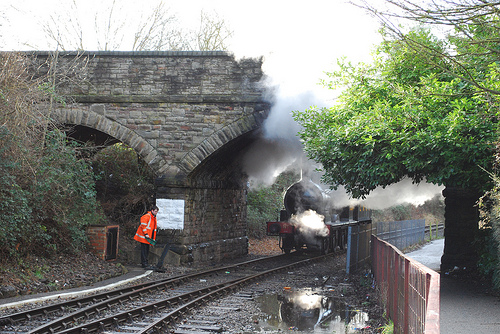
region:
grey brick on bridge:
[139, 128, 159, 138]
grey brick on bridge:
[128, 107, 143, 120]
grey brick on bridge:
[90, 102, 107, 117]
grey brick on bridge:
[171, 108, 185, 118]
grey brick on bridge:
[188, 150, 198, 164]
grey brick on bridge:
[201, 140, 215, 152]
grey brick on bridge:
[210, 131, 224, 147]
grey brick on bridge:
[86, 108, 96, 125]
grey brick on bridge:
[67, 106, 76, 123]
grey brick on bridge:
[111, 84, 126, 95]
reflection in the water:
[262, 285, 360, 332]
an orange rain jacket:
[135, 212, 160, 245]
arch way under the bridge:
[22, 107, 160, 257]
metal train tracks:
[4, 250, 331, 332]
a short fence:
[372, 233, 439, 329]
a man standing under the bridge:
[134, 203, 158, 263]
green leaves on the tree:
[299, 13, 497, 190]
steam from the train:
[286, 208, 326, 240]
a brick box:
[89, 224, 119, 257]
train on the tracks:
[267, 167, 352, 259]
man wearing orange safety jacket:
[130, 201, 170, 262]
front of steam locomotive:
[271, 150, 329, 265]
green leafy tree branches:
[300, 55, 403, 186]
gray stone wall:
[120, 57, 218, 98]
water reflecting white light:
[251, 271, 362, 327]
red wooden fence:
[378, 241, 461, 322]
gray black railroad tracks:
[101, 278, 221, 323]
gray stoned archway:
[51, 100, 178, 180]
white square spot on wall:
[152, 193, 195, 233]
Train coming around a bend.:
[275, 164, 445, 262]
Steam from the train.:
[240, 66, 442, 236]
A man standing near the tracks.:
[130, 203, 160, 269]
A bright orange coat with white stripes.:
[132, 210, 157, 245]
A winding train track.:
[20, 220, 445, 332]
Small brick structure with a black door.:
[75, 221, 116, 263]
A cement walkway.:
[402, 233, 497, 332]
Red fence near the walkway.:
[370, 234, 440, 333]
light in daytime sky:
[0, 2, 485, 50]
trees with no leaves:
[2, 1, 241, 48]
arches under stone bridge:
[2, 51, 299, 270]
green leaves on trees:
[296, 19, 496, 201]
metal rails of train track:
[7, 255, 299, 332]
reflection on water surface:
[264, 285, 357, 332]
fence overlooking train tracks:
[365, 231, 441, 331]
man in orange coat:
[134, 204, 159, 264]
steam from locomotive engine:
[254, 64, 361, 195]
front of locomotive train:
[284, 179, 327, 224]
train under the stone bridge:
[270, 165, 357, 261]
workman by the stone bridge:
[134, 203, 166, 273]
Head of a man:
[148, 203, 162, 217]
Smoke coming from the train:
[258, 80, 422, 235]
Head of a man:
[151, 205, 159, 216]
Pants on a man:
[140, 241, 152, 268]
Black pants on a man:
[136, 241, 149, 266]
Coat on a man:
[132, 210, 161, 246]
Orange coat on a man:
[131, 210, 162, 247]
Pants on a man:
[136, 242, 150, 267]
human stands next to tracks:
[132, 203, 164, 267]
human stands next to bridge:
[134, 202, 161, 268]